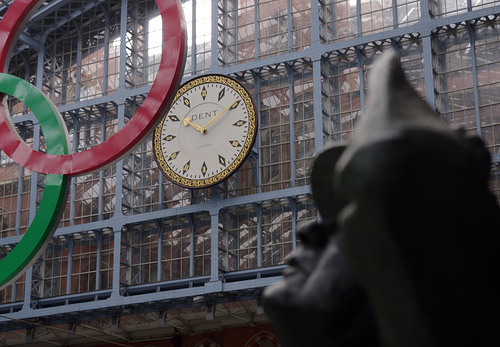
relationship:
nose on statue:
[304, 211, 333, 237] [310, 94, 427, 268]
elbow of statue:
[347, 64, 443, 174] [310, 94, 427, 268]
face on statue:
[247, 177, 370, 330] [310, 94, 427, 268]